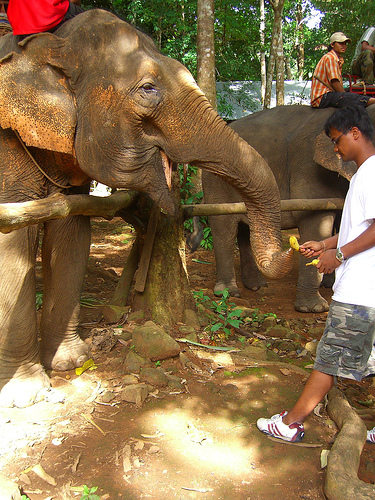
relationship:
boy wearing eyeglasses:
[256, 99, 374, 441] [331, 127, 346, 145]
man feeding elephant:
[254, 97, 373, 444] [0, 7, 294, 408]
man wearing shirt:
[254, 97, 373, 444] [329, 152, 374, 309]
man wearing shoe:
[254, 97, 373, 444] [256, 408, 307, 444]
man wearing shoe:
[254, 97, 373, 444] [363, 424, 374, 441]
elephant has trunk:
[0, 7, 294, 408] [166, 84, 301, 281]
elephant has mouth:
[0, 7, 294, 408] [153, 143, 193, 216]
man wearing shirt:
[310, 29, 374, 105] [309, 47, 346, 106]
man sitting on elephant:
[310, 29, 374, 105] [200, 103, 372, 312]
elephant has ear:
[0, 7, 294, 408] [0, 30, 77, 156]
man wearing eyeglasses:
[254, 97, 373, 444] [332, 127, 351, 145]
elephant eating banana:
[0, 7, 294, 408] [289, 234, 301, 251]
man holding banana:
[254, 97, 373, 444] [288, 235, 303, 255]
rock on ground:
[127, 316, 182, 362] [2, 213, 372, 498]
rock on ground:
[125, 349, 149, 373] [2, 213, 372, 498]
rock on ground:
[140, 366, 168, 385] [2, 213, 372, 498]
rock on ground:
[121, 379, 148, 404] [2, 213, 372, 498]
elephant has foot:
[200, 103, 372, 312] [292, 289, 330, 316]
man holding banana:
[254, 97, 373, 444] [303, 255, 320, 267]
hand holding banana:
[299, 238, 323, 260] [289, 235, 299, 251]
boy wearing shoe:
[256, 99, 374, 441] [254, 409, 304, 443]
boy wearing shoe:
[256, 99, 374, 441] [364, 425, 374, 445]